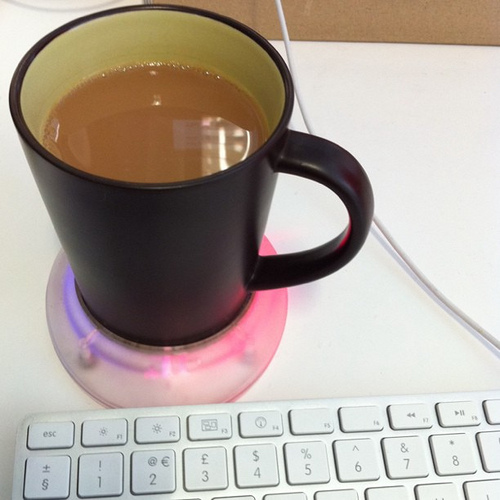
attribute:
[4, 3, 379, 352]
cup — black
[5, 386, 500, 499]
keyboard — white, european, macintosh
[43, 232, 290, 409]
cuprest — bright, illuminated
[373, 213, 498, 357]
cord — white